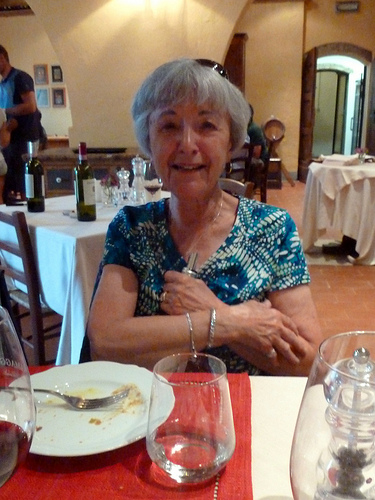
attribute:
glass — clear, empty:
[143, 350, 242, 485]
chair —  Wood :
[2, 212, 46, 365]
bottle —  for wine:
[72, 141, 97, 221]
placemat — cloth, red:
[2, 364, 249, 497]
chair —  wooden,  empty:
[0, 204, 66, 366]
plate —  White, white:
[0, 359, 176, 457]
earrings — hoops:
[223, 158, 234, 175]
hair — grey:
[122, 50, 253, 162]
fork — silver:
[3, 380, 134, 411]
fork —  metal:
[3, 381, 132, 409]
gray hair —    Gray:
[122, 51, 239, 119]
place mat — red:
[165, 371, 252, 497]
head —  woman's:
[131, 59, 250, 196]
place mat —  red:
[0, 362, 255, 498]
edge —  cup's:
[150, 361, 161, 379]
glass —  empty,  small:
[145, 352, 237, 482]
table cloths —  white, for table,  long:
[301, 150, 373, 264]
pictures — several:
[33, 65, 64, 109]